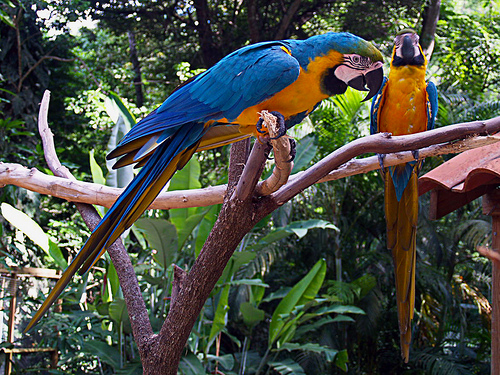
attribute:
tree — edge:
[86, 201, 281, 363]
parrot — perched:
[341, 19, 469, 349]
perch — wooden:
[9, 108, 486, 228]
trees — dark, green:
[9, 203, 480, 370]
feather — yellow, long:
[406, 237, 416, 322]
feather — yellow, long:
[395, 249, 407, 306]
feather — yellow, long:
[399, 323, 412, 361]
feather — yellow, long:
[403, 170, 418, 232]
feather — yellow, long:
[382, 171, 397, 251]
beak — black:
[365, 69, 391, 98]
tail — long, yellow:
[380, 155, 428, 368]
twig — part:
[373, 150, 391, 177]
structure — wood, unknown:
[8, 249, 103, 374]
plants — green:
[3, 0, 499, 373]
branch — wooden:
[235, 103, 295, 209]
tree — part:
[20, 87, 498, 374]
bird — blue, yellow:
[27, 21, 384, 322]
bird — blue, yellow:
[375, 31, 444, 277]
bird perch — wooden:
[27, 92, 494, 367]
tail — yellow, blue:
[22, 119, 205, 333]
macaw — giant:
[20, 30, 384, 336]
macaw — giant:
[367, 27, 438, 365]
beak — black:
[360, 64, 383, 106]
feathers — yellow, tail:
[398, 190, 419, 365]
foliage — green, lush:
[276, 243, 430, 289]